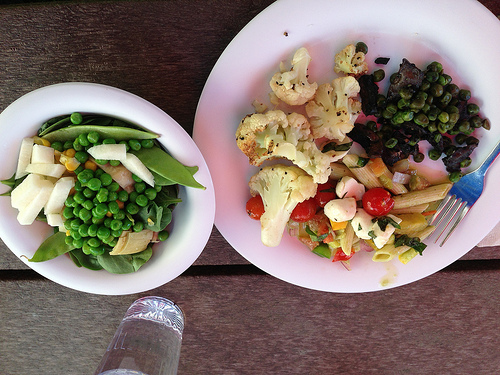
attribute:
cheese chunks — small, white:
[7, 134, 69, 234]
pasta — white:
[389, 179, 456, 213]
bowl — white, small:
[0, 77, 216, 297]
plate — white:
[194, 0, 499, 300]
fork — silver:
[425, 148, 498, 245]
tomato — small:
[359, 185, 395, 215]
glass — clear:
[93, 295, 189, 374]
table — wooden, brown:
[0, 2, 498, 370]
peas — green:
[56, 133, 171, 253]